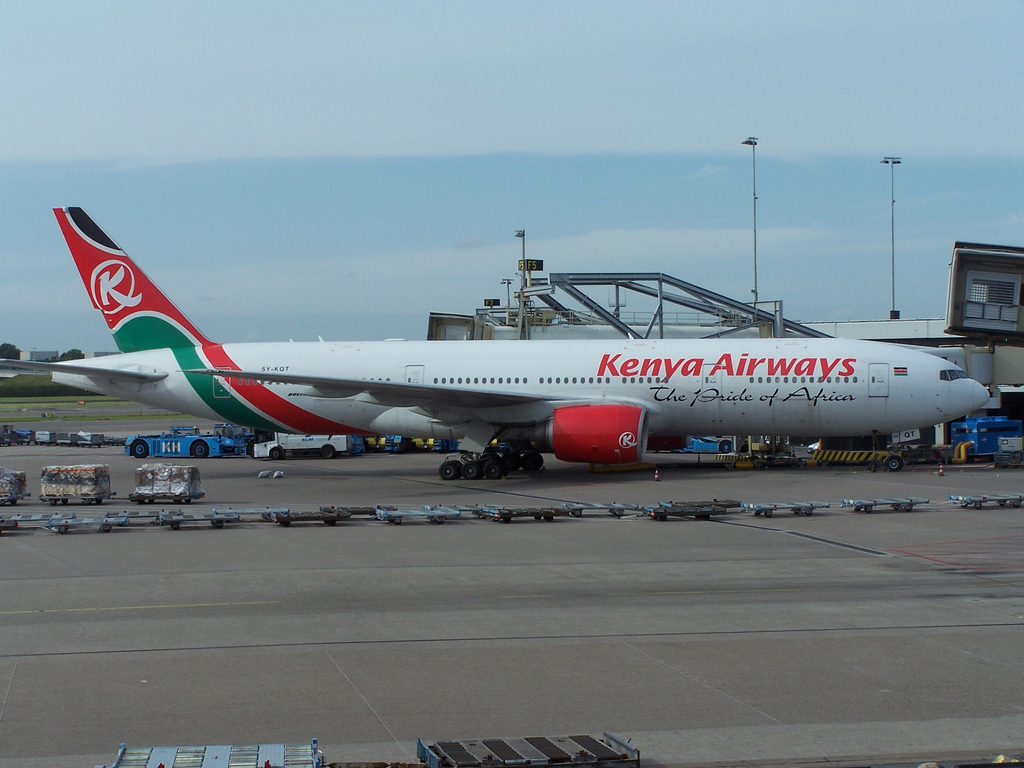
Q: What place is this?
A: It is an airport.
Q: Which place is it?
A: It is an airport.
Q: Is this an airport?
A: Yes, it is an airport.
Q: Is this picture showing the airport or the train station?
A: It is showing the airport.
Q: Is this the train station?
A: No, it is the airport.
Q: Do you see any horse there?
A: No, there are no horses.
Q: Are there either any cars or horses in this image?
A: No, there are no horses or cars.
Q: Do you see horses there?
A: No, there are no horses.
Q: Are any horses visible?
A: No, there are no horses.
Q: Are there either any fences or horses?
A: No, there are no horses or fences.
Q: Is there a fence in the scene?
A: No, there are no fences.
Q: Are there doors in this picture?
A: Yes, there is a door.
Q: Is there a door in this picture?
A: Yes, there is a door.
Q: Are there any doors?
A: Yes, there is a door.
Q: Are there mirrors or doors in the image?
A: Yes, there is a door.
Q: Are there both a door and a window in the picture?
A: Yes, there are both a door and a window.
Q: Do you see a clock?
A: No, there are no clocks.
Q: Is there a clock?
A: No, there are no clocks.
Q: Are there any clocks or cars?
A: No, there are no clocks or cars.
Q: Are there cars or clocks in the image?
A: No, there are no clocks or cars.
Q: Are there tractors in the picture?
A: Yes, there is a tractor.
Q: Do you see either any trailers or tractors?
A: Yes, there is a tractor.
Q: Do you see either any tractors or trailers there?
A: Yes, there is a tractor.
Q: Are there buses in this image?
A: No, there are no buses.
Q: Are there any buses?
A: No, there are no buses.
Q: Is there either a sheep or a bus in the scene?
A: No, there are no buses or sheep.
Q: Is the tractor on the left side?
A: Yes, the tractor is on the left of the image.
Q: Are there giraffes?
A: No, there are no giraffes.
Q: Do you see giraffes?
A: No, there are no giraffes.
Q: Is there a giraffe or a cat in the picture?
A: No, there are no giraffes or cats.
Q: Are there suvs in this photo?
A: No, there are no suvs.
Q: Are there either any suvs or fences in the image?
A: No, there are no suvs or fences.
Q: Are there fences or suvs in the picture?
A: No, there are no suvs or fences.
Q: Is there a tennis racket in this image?
A: No, there are no rackets.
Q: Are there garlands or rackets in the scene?
A: No, there are no rackets or garlands.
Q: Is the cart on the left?
A: Yes, the cart is on the left of the image.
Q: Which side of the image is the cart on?
A: The cart is on the left of the image.